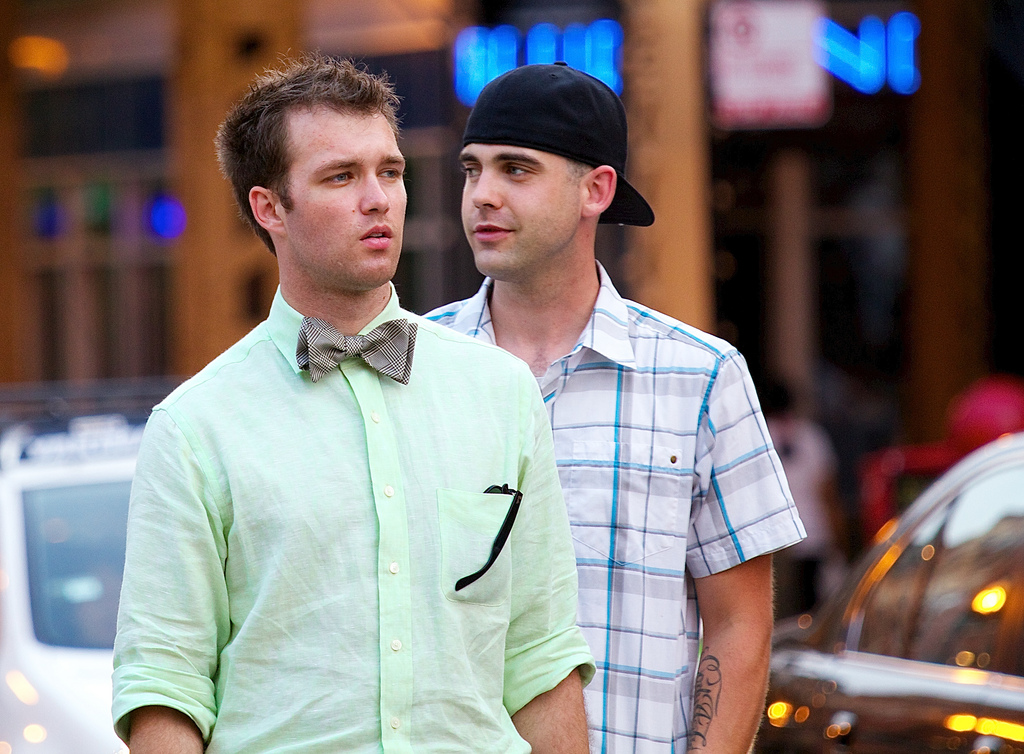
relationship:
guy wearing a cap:
[419, 62, 806, 754] [463, 61, 655, 227]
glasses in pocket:
[455, 484, 523, 592] [438, 486, 515, 607]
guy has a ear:
[110, 46, 596, 754] [243, 176, 287, 241]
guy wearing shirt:
[105, 52, 602, 750] [116, 282, 603, 743]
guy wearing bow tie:
[105, 52, 602, 750] [291, 310, 423, 384]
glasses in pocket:
[455, 484, 523, 592] [427, 478, 518, 608]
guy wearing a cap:
[414, 50, 819, 750] [463, 61, 655, 227]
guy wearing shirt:
[414, 50, 819, 750] [418, 260, 816, 744]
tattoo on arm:
[687, 646, 722, 750] [684, 350, 777, 750]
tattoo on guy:
[687, 646, 722, 750] [414, 50, 819, 750]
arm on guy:
[684, 350, 777, 750] [414, 50, 819, 750]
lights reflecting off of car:
[766, 430, 1022, 748] [753, 426, 1022, 749]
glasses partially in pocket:
[455, 484, 523, 592] [439, 485, 522, 606]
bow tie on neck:
[293, 312, 419, 379] [278, 275, 402, 360]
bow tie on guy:
[293, 312, 419, 379] [110, 46, 596, 754]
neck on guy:
[278, 275, 402, 360] [110, 46, 596, 754]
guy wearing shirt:
[110, 46, 596, 754] [116, 282, 603, 743]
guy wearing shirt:
[419, 62, 806, 754] [418, 260, 816, 744]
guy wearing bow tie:
[110, 46, 596, 754] [293, 312, 419, 379]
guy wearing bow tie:
[110, 46, 596, 754] [297, 305, 418, 381]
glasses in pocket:
[450, 482, 526, 589] [438, 486, 515, 607]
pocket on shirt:
[438, 486, 515, 607] [116, 282, 603, 743]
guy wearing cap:
[419, 62, 806, 754] [463, 61, 655, 227]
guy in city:
[105, 52, 602, 750] [5, 7, 1023, 746]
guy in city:
[414, 50, 819, 750] [5, 7, 1023, 746]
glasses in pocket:
[455, 484, 523, 592] [429, 482, 523, 597]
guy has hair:
[110, 46, 596, 754] [219, 53, 405, 261]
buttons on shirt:
[353, 363, 408, 750] [116, 282, 603, 743]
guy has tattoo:
[419, 62, 806, 754] [688, 647, 723, 749]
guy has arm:
[419, 62, 806, 754] [684, 350, 777, 750]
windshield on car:
[15, 435, 318, 658] [0, 412, 145, 754]